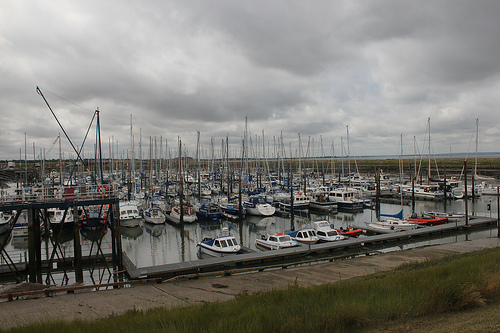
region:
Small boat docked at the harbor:
[196, 229, 244, 256]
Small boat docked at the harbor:
[252, 224, 294, 256]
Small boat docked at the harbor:
[287, 222, 317, 249]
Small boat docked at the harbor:
[307, 214, 343, 245]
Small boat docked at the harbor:
[370, 210, 415, 238]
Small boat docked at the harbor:
[400, 202, 437, 228]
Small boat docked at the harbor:
[327, 181, 369, 213]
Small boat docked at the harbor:
[309, 184, 336, 211]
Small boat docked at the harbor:
[277, 190, 317, 212]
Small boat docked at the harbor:
[242, 182, 284, 227]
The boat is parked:
[195, 225, 244, 259]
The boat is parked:
[248, 227, 296, 254]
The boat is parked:
[286, 220, 318, 245]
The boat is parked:
[307, 218, 349, 248]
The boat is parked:
[331, 214, 363, 241]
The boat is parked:
[366, 210, 409, 235]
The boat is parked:
[402, 208, 441, 228]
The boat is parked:
[113, 193, 139, 228]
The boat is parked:
[139, 195, 163, 228]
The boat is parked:
[168, 198, 198, 227]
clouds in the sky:
[1, 23, 496, 120]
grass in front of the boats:
[120, 273, 492, 319]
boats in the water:
[7, 158, 496, 241]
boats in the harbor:
[13, 148, 478, 269]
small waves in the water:
[146, 233, 191, 256]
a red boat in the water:
[411, 207, 447, 222]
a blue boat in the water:
[190, 200, 225, 219]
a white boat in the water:
[204, 227, 246, 258]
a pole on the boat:
[423, 117, 444, 179]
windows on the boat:
[219, 238, 240, 243]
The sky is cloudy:
[6, 8, 497, 147]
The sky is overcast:
[6, 7, 493, 133]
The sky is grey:
[5, 3, 498, 125]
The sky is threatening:
[8, 8, 498, 155]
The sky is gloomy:
[6, 1, 496, 131]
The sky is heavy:
[8, 6, 488, 145]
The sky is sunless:
[9, 13, 484, 141]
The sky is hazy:
[6, 3, 493, 120]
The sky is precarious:
[9, 5, 487, 137]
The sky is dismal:
[8, 10, 483, 146]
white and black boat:
[197, 233, 243, 258]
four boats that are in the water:
[196, 219, 346, 258]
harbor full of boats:
[0, 84, 497, 287]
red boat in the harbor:
[334, 221, 363, 237]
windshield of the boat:
[216, 235, 238, 247]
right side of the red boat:
[405, 210, 446, 226]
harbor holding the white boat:
[374, 218, 419, 232]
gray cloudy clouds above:
[0, 10, 495, 162]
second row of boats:
[0, 187, 381, 233]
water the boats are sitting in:
[1, 207, 386, 291]